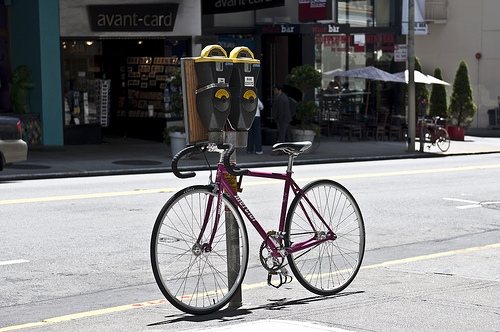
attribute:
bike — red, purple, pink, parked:
[149, 138, 367, 317]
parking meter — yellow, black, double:
[192, 42, 263, 309]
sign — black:
[84, 2, 180, 33]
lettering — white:
[97, 14, 173, 29]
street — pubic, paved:
[1, 150, 499, 329]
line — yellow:
[0, 162, 499, 205]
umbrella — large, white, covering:
[335, 66, 407, 86]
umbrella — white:
[392, 70, 452, 88]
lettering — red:
[314, 33, 398, 57]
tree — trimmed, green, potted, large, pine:
[446, 60, 476, 127]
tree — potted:
[427, 67, 448, 124]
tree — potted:
[413, 56, 430, 120]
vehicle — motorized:
[0, 115, 31, 172]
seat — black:
[273, 138, 314, 155]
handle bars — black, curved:
[171, 140, 251, 178]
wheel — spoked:
[149, 183, 250, 316]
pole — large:
[406, 0, 418, 157]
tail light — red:
[16, 120, 25, 136]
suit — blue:
[269, 92, 292, 126]